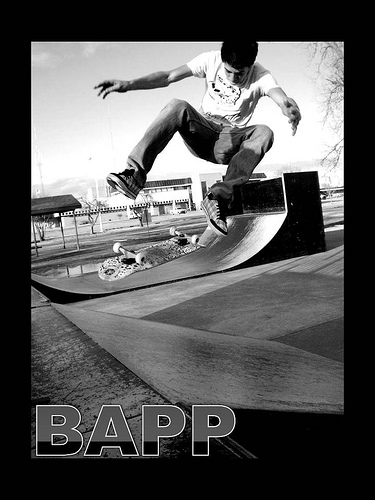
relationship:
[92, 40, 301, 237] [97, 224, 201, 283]
guy flipping skateboard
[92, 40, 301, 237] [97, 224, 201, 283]
guy playing skateboard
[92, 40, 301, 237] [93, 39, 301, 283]
guy doing kick flip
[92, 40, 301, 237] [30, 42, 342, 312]
guy in air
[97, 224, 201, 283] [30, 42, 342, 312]
skateboard in air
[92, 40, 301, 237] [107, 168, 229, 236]
guy wearing sneakers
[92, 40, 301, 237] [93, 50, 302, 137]
guy has arms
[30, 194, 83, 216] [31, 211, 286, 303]
canopy sits near ramp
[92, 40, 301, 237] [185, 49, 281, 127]
guy wearing t-shirt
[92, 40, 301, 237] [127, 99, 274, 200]
guy wearing jeans